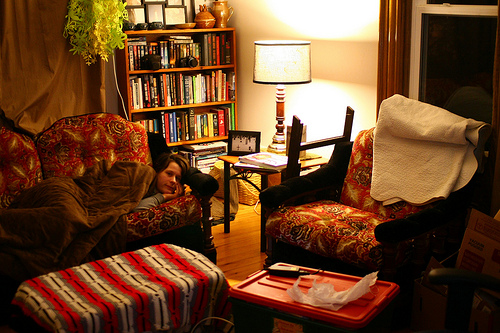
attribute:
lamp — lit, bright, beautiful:
[254, 39, 311, 151]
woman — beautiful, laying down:
[0, 154, 188, 280]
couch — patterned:
[3, 112, 218, 307]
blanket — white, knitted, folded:
[370, 93, 494, 205]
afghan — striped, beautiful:
[11, 242, 233, 332]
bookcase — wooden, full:
[116, 26, 238, 173]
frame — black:
[227, 130, 260, 159]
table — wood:
[219, 150, 328, 234]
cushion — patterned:
[263, 126, 429, 267]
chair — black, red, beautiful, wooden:
[260, 126, 467, 332]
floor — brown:
[211, 201, 304, 333]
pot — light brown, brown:
[195, 4, 215, 29]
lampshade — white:
[254, 40, 310, 85]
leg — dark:
[223, 160, 230, 232]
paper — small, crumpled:
[284, 268, 378, 310]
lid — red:
[230, 262, 400, 328]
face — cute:
[154, 161, 181, 195]